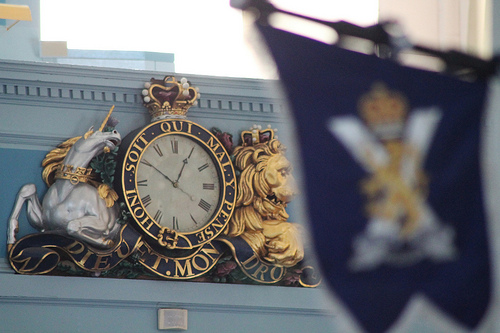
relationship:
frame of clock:
[114, 123, 198, 236] [148, 140, 202, 220]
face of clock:
[134, 140, 195, 211] [148, 140, 202, 220]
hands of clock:
[162, 163, 195, 185] [148, 140, 202, 220]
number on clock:
[142, 165, 167, 226] [148, 140, 202, 220]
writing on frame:
[117, 133, 157, 194] [114, 123, 198, 236]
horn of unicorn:
[93, 88, 122, 135] [61, 134, 117, 182]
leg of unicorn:
[11, 193, 35, 240] [61, 134, 117, 182]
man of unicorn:
[43, 143, 67, 174] [61, 134, 117, 182]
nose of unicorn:
[95, 134, 119, 147] [61, 134, 117, 182]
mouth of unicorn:
[102, 134, 142, 162] [61, 134, 117, 182]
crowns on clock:
[153, 69, 208, 121] [148, 140, 202, 220]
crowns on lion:
[153, 69, 208, 121] [235, 146, 295, 227]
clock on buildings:
[148, 140, 202, 220] [35, 31, 262, 151]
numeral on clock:
[147, 135, 205, 176] [148, 140, 202, 220]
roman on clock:
[126, 113, 179, 163] [148, 140, 202, 220]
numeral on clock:
[184, 144, 198, 162] [108, 113, 240, 252]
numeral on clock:
[193, 158, 212, 172] [108, 113, 240, 252]